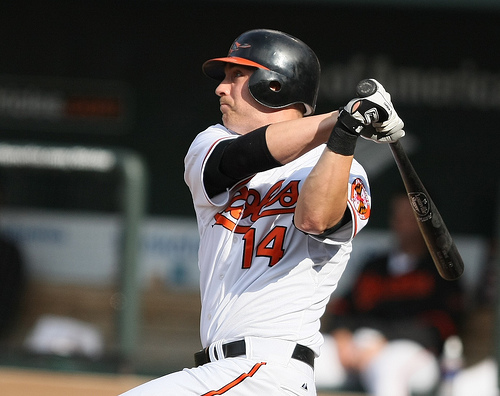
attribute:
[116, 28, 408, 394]
batter — man, hitting, right handed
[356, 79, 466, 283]
bat — black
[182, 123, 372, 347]
top — white, orange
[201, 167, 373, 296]
shadow — cast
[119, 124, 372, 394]
uniform — white, orange, clean, black trimmed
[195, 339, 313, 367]
belt — black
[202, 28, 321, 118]
helmet — black, orange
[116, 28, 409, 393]
player — playing, moving, baltimore, orioles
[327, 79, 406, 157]
gloves — white, gray, black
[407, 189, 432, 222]
writing — white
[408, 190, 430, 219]
logo — white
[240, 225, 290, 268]
number — orange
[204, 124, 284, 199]
brace — black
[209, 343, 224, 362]
loop — white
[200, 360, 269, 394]
stipe — orange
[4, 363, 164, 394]
field — baseball